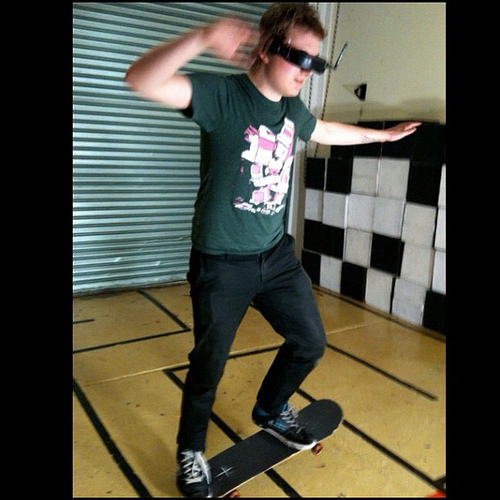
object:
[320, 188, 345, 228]
square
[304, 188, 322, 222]
square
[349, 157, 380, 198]
square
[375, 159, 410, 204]
square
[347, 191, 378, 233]
square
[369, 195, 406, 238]
square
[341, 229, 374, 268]
square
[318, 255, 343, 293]
square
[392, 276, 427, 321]
square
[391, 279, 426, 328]
square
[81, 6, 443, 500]
garage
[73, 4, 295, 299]
door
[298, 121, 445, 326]
tiles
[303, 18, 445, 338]
wall